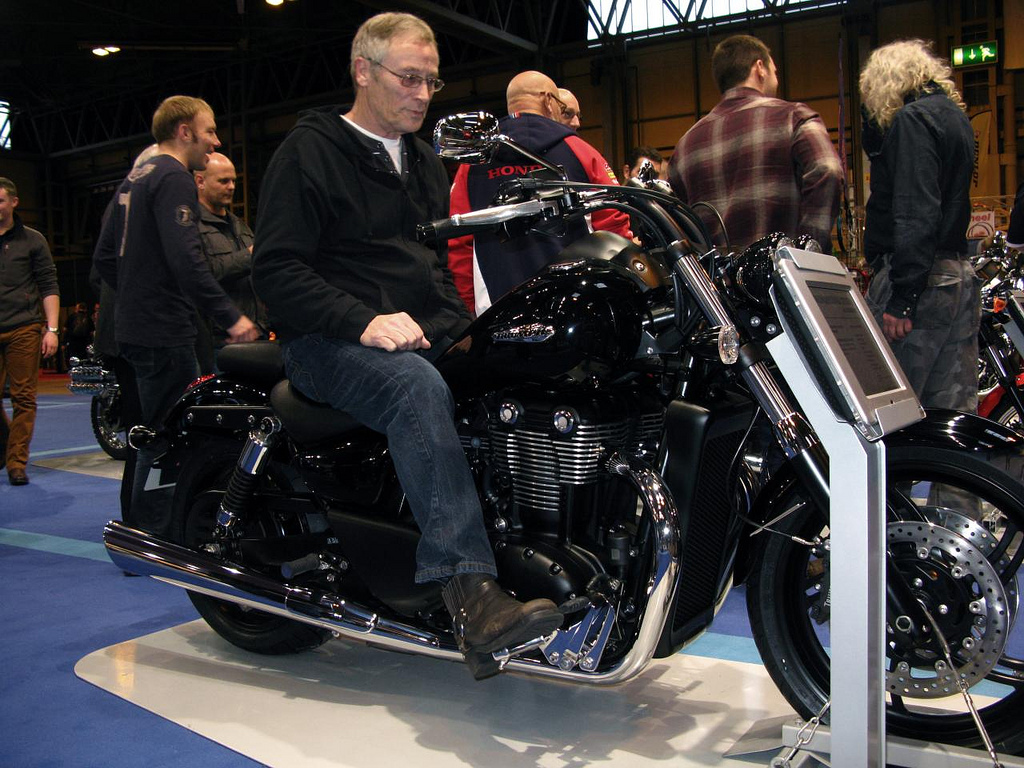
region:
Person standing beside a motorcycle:
[844, 17, 997, 438]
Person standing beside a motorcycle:
[652, 25, 849, 264]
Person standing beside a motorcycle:
[446, 61, 653, 324]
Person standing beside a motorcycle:
[1, 172, 71, 493]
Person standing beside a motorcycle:
[183, 145, 270, 351]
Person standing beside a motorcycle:
[605, 135, 685, 241]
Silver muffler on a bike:
[88, 520, 659, 716]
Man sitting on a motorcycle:
[96, 8, 1010, 742]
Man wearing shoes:
[435, 552, 573, 679]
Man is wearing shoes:
[435, 554, 569, 692]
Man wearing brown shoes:
[431, 557, 568, 687]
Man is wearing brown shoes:
[430, 555, 574, 683]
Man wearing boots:
[419, 552, 574, 689]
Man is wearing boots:
[438, 550, 562, 690]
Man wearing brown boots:
[431, 545, 571, 691]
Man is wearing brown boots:
[424, 557, 570, 687]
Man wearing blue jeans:
[269, 324, 508, 599]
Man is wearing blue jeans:
[283, 315, 518, 588]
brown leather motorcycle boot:
[440, 575, 562, 681]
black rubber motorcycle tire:
[744, 445, 1023, 759]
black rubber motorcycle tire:
[165, 442, 334, 655]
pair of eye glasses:
[365, 54, 441, 92]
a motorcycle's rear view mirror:
[430, 111, 564, 178]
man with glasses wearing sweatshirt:
[254, 12, 561, 684]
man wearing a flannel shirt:
[670, 32, 842, 248]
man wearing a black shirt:
[861, 41, 982, 418]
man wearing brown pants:
[3, 173, 62, 484]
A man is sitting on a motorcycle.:
[255, 15, 565, 682]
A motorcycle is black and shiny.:
[103, 111, 1023, 754]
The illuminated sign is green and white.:
[954, 35, 999, 71]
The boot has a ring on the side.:
[442, 576, 561, 678]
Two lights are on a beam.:
[76, 40, 232, 60]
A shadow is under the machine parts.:
[98, 525, 740, 766]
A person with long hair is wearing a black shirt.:
[849, 27, 979, 328]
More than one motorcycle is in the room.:
[68, 107, 1021, 753]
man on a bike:
[69, 13, 1019, 750]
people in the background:
[66, 0, 987, 364]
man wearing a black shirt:
[221, 100, 491, 323]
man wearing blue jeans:
[283, 300, 522, 591]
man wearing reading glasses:
[367, 57, 448, 109]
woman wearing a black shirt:
[853, 78, 1000, 322]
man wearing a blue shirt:
[68, 130, 246, 355]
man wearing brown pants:
[3, 312, 43, 469]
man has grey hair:
[343, 13, 458, 102]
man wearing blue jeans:
[103, 303, 228, 449]